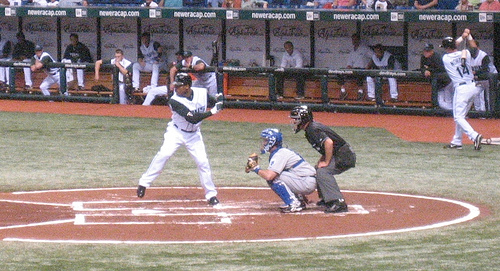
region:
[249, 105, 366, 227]
A baseball catcher and umpire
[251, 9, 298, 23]
White lettering on a green ledge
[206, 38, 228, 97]
A baseball bat in the air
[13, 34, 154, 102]
Baseball players in the dugout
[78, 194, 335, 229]
A baseball diamond home plate area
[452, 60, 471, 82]
The number 14 on a shirt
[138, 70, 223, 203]
A batter getting prepared for the pitch.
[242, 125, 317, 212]
A catcher in front of the umpire.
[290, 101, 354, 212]
The umpire waiting for the pitch.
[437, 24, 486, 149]
A batter getting warmed up.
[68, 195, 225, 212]
The batter's box.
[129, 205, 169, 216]
Home plate.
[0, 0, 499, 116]
A dugout with player's watching the game.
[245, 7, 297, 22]
A website being advertised.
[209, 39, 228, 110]
A baseball bat.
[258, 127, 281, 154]
A helmet on the catcher.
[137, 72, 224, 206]
man getting ready to bat a baseball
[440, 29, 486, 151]
man swinging bat for practice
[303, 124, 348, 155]
umpire wearing a black shirt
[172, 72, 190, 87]
black hat batter is wearing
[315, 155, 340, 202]
umpire is wearing gray pants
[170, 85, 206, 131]
black and white top the batter is wearing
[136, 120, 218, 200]
white pants worned by the batter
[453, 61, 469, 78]
black number on a white top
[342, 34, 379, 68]
man standing behind the counter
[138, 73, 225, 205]
the batter is ready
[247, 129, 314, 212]
the catcher is in blue and white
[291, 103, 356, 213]
umpire is all in black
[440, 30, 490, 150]
number 14 is waiting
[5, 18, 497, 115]
the dugout is green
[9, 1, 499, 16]
the people in the stands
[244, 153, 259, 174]
the catchers mit is brown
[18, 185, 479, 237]
the base is in a circle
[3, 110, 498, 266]
the field is green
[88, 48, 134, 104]
the guy hanging on the fence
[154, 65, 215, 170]
a man playing baseball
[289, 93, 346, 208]
a man playing baseball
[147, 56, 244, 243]
a man holding bat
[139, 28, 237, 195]
a man holding a baseball bat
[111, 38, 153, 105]
a man sitting in dugout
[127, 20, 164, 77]
a man sitting in dugout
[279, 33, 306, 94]
a man sitting in dugout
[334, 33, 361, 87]
a man sitting in dugout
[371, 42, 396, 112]
a man sitting in dugout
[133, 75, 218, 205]
Player hitting a ball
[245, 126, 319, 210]
Catcher crouching at home base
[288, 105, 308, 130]
Black helmet on a man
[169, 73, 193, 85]
Black helmet on a batter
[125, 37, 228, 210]
left handed batter in swing position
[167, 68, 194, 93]
black sports safety helmet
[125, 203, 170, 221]
home plate between batter's boxes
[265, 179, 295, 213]
blue catcher's safety pads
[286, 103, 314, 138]
umpires black safety gear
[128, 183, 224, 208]
men's black athletic footwear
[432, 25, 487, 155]
male batter practicing swinging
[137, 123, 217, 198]
The baseball player is wearing white pants.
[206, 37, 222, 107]
The baseball player is holding a black bat.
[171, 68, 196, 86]
The baseball player is wearing a black helmet.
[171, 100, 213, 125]
The baseball player is wearing black sleeves.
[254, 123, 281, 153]
The catcher is wearing a blue helmet.